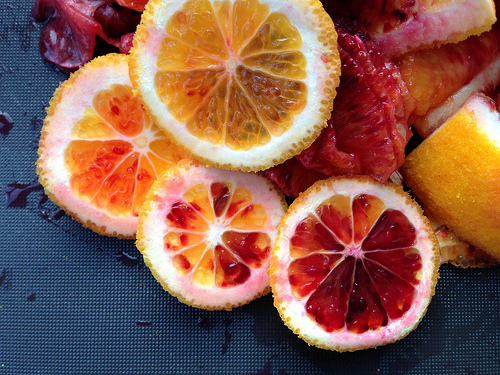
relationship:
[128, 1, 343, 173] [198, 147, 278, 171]
lemon has peel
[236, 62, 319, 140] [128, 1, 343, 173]
slice of lemon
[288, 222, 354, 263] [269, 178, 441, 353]
section of orange